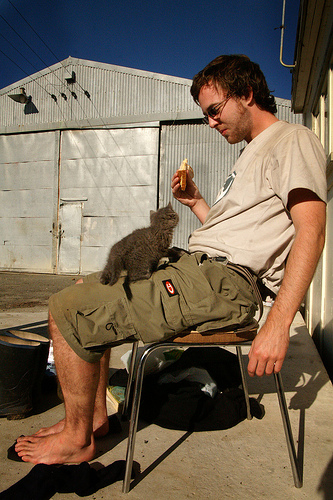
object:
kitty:
[99, 201, 180, 288]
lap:
[47, 265, 245, 352]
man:
[14, 52, 326, 471]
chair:
[118, 333, 306, 498]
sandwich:
[178, 158, 194, 192]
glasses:
[201, 92, 235, 126]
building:
[1, 50, 331, 272]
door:
[2, 129, 164, 278]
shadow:
[26, 463, 78, 500]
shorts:
[47, 245, 262, 367]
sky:
[6, 2, 258, 59]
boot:
[0, 334, 42, 423]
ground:
[156, 434, 285, 500]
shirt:
[187, 118, 329, 299]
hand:
[170, 170, 201, 207]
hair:
[189, 46, 278, 114]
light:
[6, 86, 33, 105]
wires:
[0, 3, 94, 106]